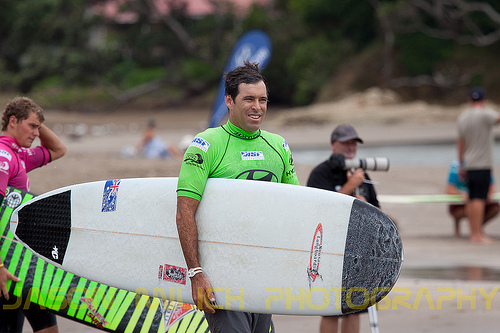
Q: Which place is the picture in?
A: It is at the beach.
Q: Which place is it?
A: It is a beach.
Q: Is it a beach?
A: Yes, it is a beach.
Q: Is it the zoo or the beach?
A: It is the beach.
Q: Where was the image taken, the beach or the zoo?
A: It was taken at the beach.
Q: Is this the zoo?
A: No, it is the beach.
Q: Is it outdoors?
A: Yes, it is outdoors.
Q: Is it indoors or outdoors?
A: It is outdoors.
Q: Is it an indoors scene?
A: No, it is outdoors.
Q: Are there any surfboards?
A: Yes, there is a surfboard.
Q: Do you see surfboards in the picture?
A: Yes, there is a surfboard.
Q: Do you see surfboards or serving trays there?
A: Yes, there is a surfboard.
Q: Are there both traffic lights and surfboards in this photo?
A: No, there is a surfboard but no traffic lights.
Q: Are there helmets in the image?
A: No, there are no helmets.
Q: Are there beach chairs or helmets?
A: No, there are no helmets or beach chairs.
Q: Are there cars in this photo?
A: No, there are no cars.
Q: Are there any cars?
A: No, there are no cars.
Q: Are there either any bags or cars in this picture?
A: No, there are no cars or bags.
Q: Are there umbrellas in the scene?
A: No, there are no umbrellas.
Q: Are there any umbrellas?
A: No, there are no umbrellas.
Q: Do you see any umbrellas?
A: No, there are no umbrellas.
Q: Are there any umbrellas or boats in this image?
A: No, there are no umbrellas or boats.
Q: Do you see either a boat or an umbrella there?
A: No, there are no umbrellas or boats.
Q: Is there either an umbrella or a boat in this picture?
A: No, there are no umbrellas or boats.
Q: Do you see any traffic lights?
A: No, there are no traffic lights.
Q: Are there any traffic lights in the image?
A: No, there are no traffic lights.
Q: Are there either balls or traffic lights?
A: No, there are no traffic lights or balls.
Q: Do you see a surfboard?
A: Yes, there is a surfboard.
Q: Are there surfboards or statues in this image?
A: Yes, there is a surfboard.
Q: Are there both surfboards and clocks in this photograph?
A: No, there is a surfboard but no clocks.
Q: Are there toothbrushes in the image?
A: No, there are no toothbrushes.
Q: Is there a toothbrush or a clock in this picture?
A: No, there are no toothbrushes or clocks.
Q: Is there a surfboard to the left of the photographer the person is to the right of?
A: Yes, there is a surfboard to the left of the photographer.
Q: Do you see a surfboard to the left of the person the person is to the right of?
A: Yes, there is a surfboard to the left of the photographer.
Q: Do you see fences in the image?
A: No, there are no fences.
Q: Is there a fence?
A: No, there are no fences.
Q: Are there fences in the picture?
A: No, there are no fences.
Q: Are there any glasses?
A: No, there are no glasses.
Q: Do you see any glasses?
A: No, there are no glasses.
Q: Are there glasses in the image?
A: No, there are no glasses.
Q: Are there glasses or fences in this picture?
A: No, there are no glasses or fences.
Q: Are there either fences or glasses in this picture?
A: No, there are no glasses or fences.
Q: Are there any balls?
A: No, there are no balls.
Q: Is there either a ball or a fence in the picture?
A: No, there are no balls or fences.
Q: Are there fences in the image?
A: No, there are no fences.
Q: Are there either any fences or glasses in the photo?
A: No, there are no fences or glasses.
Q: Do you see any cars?
A: No, there are no cars.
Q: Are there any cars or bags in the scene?
A: No, there are no cars or bags.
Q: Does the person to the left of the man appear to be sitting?
A: Yes, the person is sitting.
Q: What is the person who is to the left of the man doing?
A: The person is sitting.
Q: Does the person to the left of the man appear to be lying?
A: No, the person is sitting.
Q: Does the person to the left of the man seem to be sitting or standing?
A: The person is sitting.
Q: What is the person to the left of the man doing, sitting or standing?
A: The person is sitting.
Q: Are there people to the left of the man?
A: Yes, there is a person to the left of the man.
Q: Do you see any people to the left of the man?
A: Yes, there is a person to the left of the man.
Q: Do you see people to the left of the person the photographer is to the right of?
A: Yes, there is a person to the left of the man.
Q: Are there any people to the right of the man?
A: No, the person is to the left of the man.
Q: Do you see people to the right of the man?
A: No, the person is to the left of the man.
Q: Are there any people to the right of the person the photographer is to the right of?
A: No, the person is to the left of the man.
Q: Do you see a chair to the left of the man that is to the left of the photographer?
A: No, there is a person to the left of the man.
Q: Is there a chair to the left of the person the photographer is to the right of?
A: No, there is a person to the left of the man.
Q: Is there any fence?
A: No, there are no fences.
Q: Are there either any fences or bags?
A: No, there are no fences or bags.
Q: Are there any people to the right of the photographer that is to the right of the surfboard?
A: Yes, there is a person to the right of the photographer.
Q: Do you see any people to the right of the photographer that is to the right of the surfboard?
A: Yes, there is a person to the right of the photographer.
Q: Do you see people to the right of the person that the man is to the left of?
A: Yes, there is a person to the right of the photographer.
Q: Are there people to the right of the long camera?
A: Yes, there is a person to the right of the camera.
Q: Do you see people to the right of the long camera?
A: Yes, there is a person to the right of the camera.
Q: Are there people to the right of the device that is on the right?
A: Yes, there is a person to the right of the camera.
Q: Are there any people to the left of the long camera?
A: No, the person is to the right of the camera.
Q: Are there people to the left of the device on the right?
A: No, the person is to the right of the camera.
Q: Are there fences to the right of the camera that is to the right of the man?
A: No, there is a person to the right of the camera.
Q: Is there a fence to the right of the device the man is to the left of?
A: No, there is a person to the right of the camera.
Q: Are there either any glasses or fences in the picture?
A: No, there are no fences or glasses.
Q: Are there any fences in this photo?
A: No, there are no fences.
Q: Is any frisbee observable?
A: No, there are no frisbees.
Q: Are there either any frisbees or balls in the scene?
A: No, there are no frisbees or balls.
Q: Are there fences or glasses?
A: No, there are no fences or glasses.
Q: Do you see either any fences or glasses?
A: No, there are no fences or glasses.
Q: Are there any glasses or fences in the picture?
A: No, there are no fences or glasses.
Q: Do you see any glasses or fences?
A: No, there are no fences or glasses.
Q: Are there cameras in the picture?
A: Yes, there is a camera.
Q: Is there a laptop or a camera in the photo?
A: Yes, there is a camera.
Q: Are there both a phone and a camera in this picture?
A: No, there is a camera but no phones.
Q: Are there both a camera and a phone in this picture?
A: No, there is a camera but no phones.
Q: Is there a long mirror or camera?
A: Yes, there is a long camera.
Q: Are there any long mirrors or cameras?
A: Yes, there is a long camera.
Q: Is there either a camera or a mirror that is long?
A: Yes, the camera is long.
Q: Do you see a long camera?
A: Yes, there is a long camera.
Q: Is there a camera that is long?
A: Yes, there is a camera that is long.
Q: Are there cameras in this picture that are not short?
A: Yes, there is a long camera.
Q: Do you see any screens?
A: No, there are no screens.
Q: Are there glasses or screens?
A: No, there are no screens or glasses.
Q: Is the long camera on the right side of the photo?
A: Yes, the camera is on the right of the image.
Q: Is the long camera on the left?
A: No, the camera is on the right of the image.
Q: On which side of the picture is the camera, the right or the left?
A: The camera is on the right of the image.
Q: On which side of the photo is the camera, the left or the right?
A: The camera is on the right of the image.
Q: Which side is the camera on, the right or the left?
A: The camera is on the right of the image.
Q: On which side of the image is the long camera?
A: The camera is on the right of the image.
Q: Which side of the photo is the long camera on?
A: The camera is on the right of the image.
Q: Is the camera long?
A: Yes, the camera is long.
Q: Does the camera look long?
A: Yes, the camera is long.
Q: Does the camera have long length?
A: Yes, the camera is long.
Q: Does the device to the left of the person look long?
A: Yes, the camera is long.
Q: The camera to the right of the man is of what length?
A: The camera is long.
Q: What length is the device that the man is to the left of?
A: The camera is long.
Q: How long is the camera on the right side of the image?
A: The camera is long.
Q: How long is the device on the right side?
A: The camera is long.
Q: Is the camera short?
A: No, the camera is long.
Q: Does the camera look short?
A: No, the camera is long.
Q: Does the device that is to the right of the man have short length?
A: No, the camera is long.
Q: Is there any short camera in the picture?
A: No, there is a camera but it is long.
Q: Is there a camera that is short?
A: No, there is a camera but it is long.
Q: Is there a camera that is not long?
A: No, there is a camera but it is long.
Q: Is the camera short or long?
A: The camera is long.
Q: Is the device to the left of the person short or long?
A: The camera is long.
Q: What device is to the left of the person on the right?
A: The device is a camera.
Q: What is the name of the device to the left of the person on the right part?
A: The device is a camera.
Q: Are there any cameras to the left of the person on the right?
A: Yes, there is a camera to the left of the person.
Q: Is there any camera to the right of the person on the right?
A: No, the camera is to the left of the person.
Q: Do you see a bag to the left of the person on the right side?
A: No, there is a camera to the left of the person.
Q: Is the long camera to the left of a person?
A: Yes, the camera is to the left of a person.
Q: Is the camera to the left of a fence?
A: No, the camera is to the left of a person.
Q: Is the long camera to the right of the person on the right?
A: No, the camera is to the left of the person.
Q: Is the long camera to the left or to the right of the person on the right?
A: The camera is to the left of the person.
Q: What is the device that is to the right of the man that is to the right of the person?
A: The device is a camera.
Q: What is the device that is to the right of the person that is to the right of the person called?
A: The device is a camera.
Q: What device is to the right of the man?
A: The device is a camera.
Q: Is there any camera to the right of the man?
A: Yes, there is a camera to the right of the man.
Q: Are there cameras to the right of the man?
A: Yes, there is a camera to the right of the man.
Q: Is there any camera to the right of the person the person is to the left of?
A: Yes, there is a camera to the right of the man.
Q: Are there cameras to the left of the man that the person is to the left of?
A: No, the camera is to the right of the man.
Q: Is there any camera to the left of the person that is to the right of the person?
A: No, the camera is to the right of the man.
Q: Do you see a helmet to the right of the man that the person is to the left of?
A: No, there is a camera to the right of the man.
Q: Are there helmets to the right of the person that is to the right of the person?
A: No, there is a camera to the right of the man.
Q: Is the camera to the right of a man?
A: Yes, the camera is to the right of a man.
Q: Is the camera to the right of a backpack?
A: No, the camera is to the right of a man.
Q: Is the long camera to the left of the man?
A: No, the camera is to the right of the man.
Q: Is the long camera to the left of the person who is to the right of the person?
A: No, the camera is to the right of the man.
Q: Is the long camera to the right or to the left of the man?
A: The camera is to the right of the man.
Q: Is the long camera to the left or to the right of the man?
A: The camera is to the right of the man.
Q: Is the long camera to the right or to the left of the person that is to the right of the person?
A: The camera is to the right of the man.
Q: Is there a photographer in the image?
A: Yes, there is a photographer.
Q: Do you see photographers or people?
A: Yes, there is a photographer.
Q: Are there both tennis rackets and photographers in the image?
A: No, there is a photographer but no rackets.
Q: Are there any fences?
A: No, there are no fences.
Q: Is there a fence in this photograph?
A: No, there are no fences.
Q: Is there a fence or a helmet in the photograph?
A: No, there are no fences or helmets.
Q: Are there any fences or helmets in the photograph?
A: No, there are no fences or helmets.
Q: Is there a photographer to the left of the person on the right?
A: Yes, there is a photographer to the left of the person.